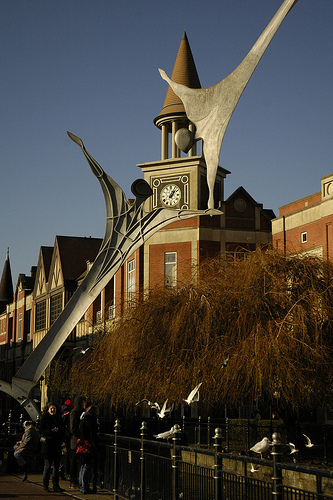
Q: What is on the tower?
A: A clock.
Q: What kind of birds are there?
A: Seaguls.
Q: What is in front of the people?
A: A fence.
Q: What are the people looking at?
A: The birds.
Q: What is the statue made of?
A: Metal.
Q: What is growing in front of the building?
A: A tree.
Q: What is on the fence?
A: A bird.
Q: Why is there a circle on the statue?
A: Head.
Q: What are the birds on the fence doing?
A: Sitting.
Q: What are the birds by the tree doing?
A: Flying.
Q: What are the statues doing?
A: Reaching for each other.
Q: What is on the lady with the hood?
A: Red bag.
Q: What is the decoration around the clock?
A: Circles and rectangles.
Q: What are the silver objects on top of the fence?
A: Posts.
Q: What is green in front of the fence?
A: Grass.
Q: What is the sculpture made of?
A: The sculpture is made of metal.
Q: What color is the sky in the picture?
A: Blue.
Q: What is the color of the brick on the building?
A: Red.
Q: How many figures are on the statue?
A: Two.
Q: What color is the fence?
A: Black.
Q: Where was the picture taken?
A: A park.